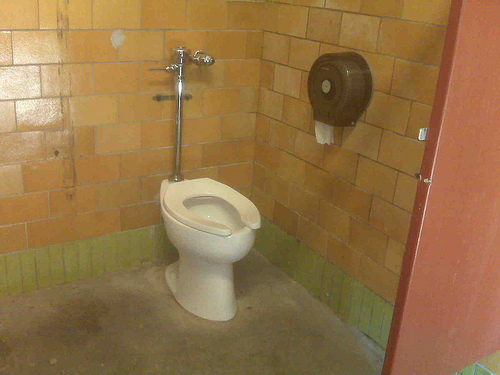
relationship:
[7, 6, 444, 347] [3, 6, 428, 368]
grout on wall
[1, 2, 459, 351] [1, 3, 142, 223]
tile on wall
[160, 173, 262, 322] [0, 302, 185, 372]
toilet on floor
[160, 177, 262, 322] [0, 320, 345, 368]
toilet on floor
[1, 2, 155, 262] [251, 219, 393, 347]
tile on bottom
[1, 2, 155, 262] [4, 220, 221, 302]
tile on bottom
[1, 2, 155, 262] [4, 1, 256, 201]
tile on wall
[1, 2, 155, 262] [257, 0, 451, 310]
tile on wall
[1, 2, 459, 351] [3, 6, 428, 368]
tile on wall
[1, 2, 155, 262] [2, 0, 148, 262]
tile on wall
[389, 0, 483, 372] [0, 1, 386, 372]
bathroom stahl in bathroom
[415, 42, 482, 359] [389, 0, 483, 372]
door in bathroom stahl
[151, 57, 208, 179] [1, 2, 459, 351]
pipe on tile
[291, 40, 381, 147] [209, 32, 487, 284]
toilet paper on wall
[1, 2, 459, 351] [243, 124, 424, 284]
tile on wall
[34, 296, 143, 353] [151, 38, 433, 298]
stain on wall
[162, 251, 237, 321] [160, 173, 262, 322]
base of toilet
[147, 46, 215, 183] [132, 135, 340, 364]
pipe on toilet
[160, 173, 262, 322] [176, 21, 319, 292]
toilet in corner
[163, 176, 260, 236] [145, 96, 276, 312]
seat of toilet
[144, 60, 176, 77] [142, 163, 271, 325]
handle on toilet